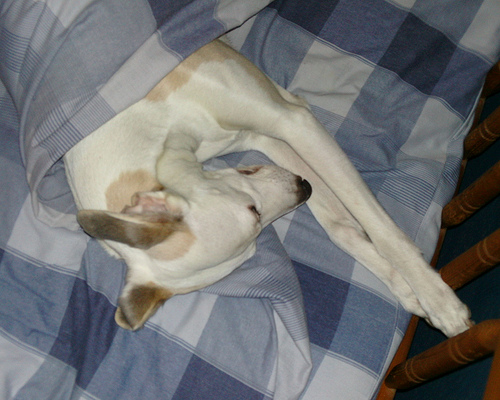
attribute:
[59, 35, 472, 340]
dog — sleeping, brown, white, laying down, tan, laying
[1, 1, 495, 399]
sheets — blue, plaid, white, checkered, blue plaid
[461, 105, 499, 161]
railing — brown, wooden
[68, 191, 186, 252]
ear — brown, light brown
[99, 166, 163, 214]
spot — brown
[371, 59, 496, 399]
headboard — wooden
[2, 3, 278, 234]
sheet — checkered, blue, white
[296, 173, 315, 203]
nose — black, wet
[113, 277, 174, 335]
ear — brown, light brown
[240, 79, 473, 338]
front leg — white, outstretched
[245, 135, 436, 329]
front leg — white, outstretched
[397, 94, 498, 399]
carpet — blue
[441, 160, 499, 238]
rung — brown, wooden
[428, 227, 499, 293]
rung — brown, wooden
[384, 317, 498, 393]
rung — brown, wooden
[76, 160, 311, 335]
head — white, tan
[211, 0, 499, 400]
sheet — blue, white